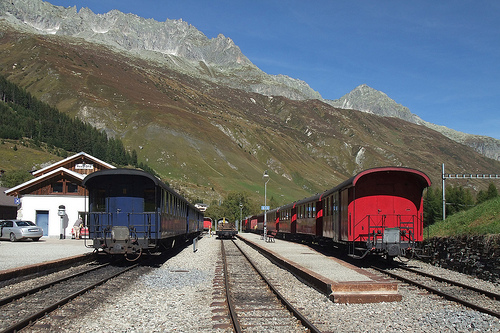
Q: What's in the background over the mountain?
A: Blue sky.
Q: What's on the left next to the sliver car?
A: A brown and white building.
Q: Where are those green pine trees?
A: On a hill on the left.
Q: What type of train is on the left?
A: Caboose train.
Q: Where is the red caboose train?
A: On the right track.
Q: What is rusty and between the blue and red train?
A: A set of train tracks.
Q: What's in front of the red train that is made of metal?
A: A set of train tracks.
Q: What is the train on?
A: On train tracks.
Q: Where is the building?
A: Next to the blue train.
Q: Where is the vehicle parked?
A: Next to the building.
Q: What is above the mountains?
A: A blue sky.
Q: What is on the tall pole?
A: A street light.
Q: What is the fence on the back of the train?
A: Metal.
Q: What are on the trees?
A: Green leaves.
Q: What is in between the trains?
A: Sidewalk.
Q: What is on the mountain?
A: Grass.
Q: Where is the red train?
A: On the tracks.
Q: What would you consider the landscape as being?
A: Mountainous.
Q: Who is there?
A: No one.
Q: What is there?
A: Trains.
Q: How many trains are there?
A: 2.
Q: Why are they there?
A: Transport.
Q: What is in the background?
A: Mountains.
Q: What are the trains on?
A: Railroad tracks.